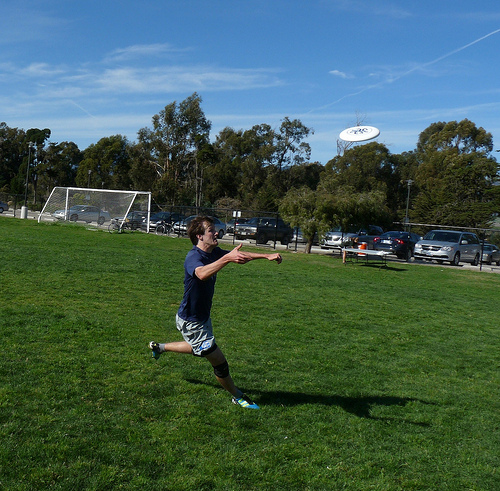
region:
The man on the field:
[145, 219, 284, 416]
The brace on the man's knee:
[212, 354, 233, 376]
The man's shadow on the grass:
[180, 364, 452, 434]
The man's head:
[182, 206, 222, 250]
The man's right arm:
[185, 242, 250, 282]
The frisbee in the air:
[334, 119, 384, 148]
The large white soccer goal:
[34, 179, 161, 236]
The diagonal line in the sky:
[294, 25, 499, 121]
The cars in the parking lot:
[50, 201, 497, 269]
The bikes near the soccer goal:
[100, 213, 183, 243]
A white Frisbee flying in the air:
[303, 73, 392, 150]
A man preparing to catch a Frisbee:
[140, 186, 287, 425]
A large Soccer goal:
[48, 169, 145, 244]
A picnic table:
[337, 243, 389, 279]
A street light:
[397, 160, 417, 230]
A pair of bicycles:
[100, 201, 175, 241]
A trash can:
[16, 195, 23, 226]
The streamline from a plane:
[305, 25, 491, 117]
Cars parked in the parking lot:
[260, 205, 466, 275]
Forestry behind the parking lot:
[32, 105, 358, 212]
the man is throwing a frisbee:
[135, 96, 400, 470]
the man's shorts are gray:
[166, 303, 241, 370]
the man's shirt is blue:
[175, 237, 238, 339]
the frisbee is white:
[320, 111, 404, 158]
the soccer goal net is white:
[30, 171, 163, 243]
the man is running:
[135, 199, 307, 468]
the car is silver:
[412, 207, 492, 277]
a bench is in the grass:
[321, 233, 397, 279]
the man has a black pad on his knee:
[201, 349, 243, 387]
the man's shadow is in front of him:
[176, 343, 464, 447]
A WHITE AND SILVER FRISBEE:
[335, 119, 387, 148]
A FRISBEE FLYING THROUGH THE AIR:
[334, 120, 387, 152]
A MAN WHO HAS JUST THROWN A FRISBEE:
[141, 199, 296, 421]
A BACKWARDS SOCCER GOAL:
[32, 177, 163, 239]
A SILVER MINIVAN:
[410, 220, 486, 270]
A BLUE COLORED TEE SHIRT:
[173, 240, 237, 331]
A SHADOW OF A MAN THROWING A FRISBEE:
[173, 360, 457, 445]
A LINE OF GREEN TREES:
[0, 88, 495, 258]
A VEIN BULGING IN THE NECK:
[197, 237, 214, 255]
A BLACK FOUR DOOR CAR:
[370, 222, 428, 264]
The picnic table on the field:
[334, 245, 394, 268]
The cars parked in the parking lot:
[52, 200, 499, 268]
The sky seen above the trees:
[0, 0, 498, 165]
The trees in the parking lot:
[3, 84, 498, 243]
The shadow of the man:
[186, 365, 456, 437]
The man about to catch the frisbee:
[146, 201, 293, 417]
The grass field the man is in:
[0, 211, 499, 490]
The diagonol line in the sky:
[306, 21, 498, 121]